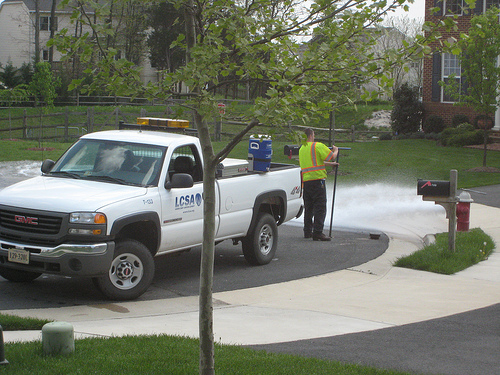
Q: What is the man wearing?
A: A yellow vest.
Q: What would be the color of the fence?
A: Brown.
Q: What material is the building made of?
A: Bricks.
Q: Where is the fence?
A: Lining the yard.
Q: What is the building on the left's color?
A: Tan.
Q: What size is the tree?
A: Thin.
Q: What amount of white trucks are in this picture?
A: 1.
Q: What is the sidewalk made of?
A: Concrete.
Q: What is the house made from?
A: Bricks.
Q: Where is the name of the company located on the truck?
A: Door.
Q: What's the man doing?
A: Taking measurements.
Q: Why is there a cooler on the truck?
A: Hydration.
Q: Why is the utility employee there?
A: Water leak.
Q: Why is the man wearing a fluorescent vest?
A: Safety.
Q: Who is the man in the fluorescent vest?
A: Utility employee.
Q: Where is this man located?
A: Residential area.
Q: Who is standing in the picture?
A: A man.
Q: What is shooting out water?
A: A fire hydrant.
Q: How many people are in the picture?
A: One.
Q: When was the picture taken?
A: During the day.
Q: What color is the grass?
A: Green.